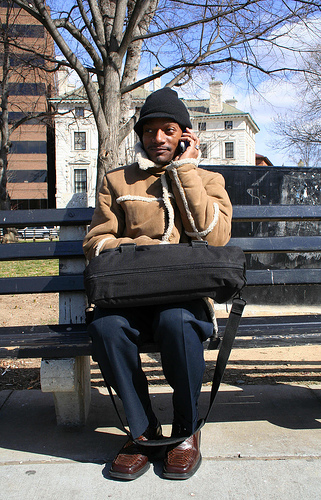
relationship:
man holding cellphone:
[93, 86, 239, 303] [177, 142, 191, 154]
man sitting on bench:
[93, 86, 239, 303] [248, 201, 315, 300]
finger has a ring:
[186, 133, 198, 148] [189, 141, 200, 148]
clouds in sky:
[237, 66, 295, 117] [187, 16, 237, 41]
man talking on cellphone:
[93, 86, 239, 303] [177, 142, 191, 154]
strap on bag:
[206, 306, 238, 369] [89, 245, 241, 296]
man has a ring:
[93, 86, 239, 303] [189, 141, 200, 148]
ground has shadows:
[215, 434, 275, 461] [227, 388, 298, 408]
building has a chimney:
[201, 90, 253, 163] [206, 74, 231, 114]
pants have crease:
[102, 321, 205, 424] [173, 330, 194, 380]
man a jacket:
[93, 86, 239, 303] [101, 179, 224, 234]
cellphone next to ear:
[177, 142, 191, 154] [181, 127, 191, 139]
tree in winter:
[58, 14, 135, 123] [14, 9, 310, 289]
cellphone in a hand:
[177, 142, 191, 154] [183, 149, 201, 158]